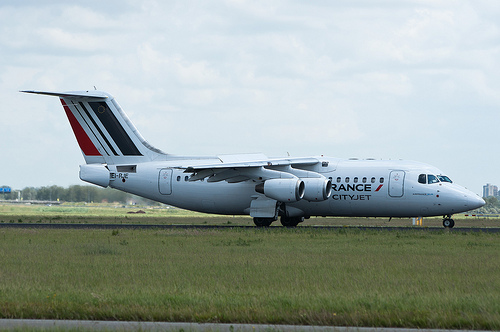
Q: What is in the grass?
A: Plane.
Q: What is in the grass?
A: Airplane.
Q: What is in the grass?
A: Wheels.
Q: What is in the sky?
A: Clouds.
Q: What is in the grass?
A: Plane.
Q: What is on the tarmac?
A: A jet.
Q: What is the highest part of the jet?
A: The tail.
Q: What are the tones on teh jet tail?
A: Red and blue.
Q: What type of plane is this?
A: Passenger.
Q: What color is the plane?
A: White.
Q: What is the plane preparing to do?
A: Take off.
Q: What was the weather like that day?
A: Cloudy.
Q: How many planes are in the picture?
A: One.